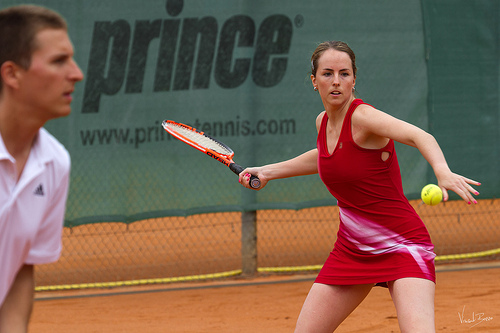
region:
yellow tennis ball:
[420, 180, 445, 206]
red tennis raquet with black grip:
[160, 121, 261, 189]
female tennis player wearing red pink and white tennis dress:
[162, 41, 477, 331]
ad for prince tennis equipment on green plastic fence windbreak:
[73, 0, 305, 151]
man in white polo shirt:
[0, 2, 83, 331]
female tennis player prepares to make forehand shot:
[162, 42, 498, 331]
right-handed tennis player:
[155, 43, 477, 331]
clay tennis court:
[0, 1, 498, 331]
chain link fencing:
[35, 198, 499, 300]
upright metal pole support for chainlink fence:
[240, 209, 257, 280]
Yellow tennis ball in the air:
[416, 183, 447, 204]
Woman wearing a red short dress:
[312, 102, 442, 284]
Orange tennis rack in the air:
[157, 110, 268, 190]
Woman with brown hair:
[310, 38, 359, 114]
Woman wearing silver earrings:
[303, 67, 357, 99]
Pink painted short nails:
[438, 176, 494, 207]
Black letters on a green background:
[77, 0, 305, 111]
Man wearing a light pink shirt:
[0, 120, 77, 312]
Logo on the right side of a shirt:
[33, 179, 45, 202]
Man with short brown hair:
[0, 7, 82, 142]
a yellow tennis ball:
[419, 183, 444, 206]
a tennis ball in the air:
[417, 180, 444, 207]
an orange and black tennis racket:
[160, 117, 261, 191]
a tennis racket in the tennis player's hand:
[158, 118, 269, 193]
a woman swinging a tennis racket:
[157, 40, 482, 331]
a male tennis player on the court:
[1, 5, 87, 331]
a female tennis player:
[159, 41, 484, 331]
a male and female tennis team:
[2, 6, 482, 331]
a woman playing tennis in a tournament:
[157, 5, 482, 332]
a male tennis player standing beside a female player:
[1, 5, 85, 332]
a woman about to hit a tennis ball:
[162, 40, 480, 332]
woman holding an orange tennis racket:
[163, 116, 261, 191]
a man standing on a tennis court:
[2, 8, 84, 332]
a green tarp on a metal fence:
[3, 0, 499, 225]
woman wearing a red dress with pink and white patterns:
[312, 95, 437, 283]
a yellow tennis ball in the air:
[421, 184, 443, 206]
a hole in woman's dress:
[381, 150, 391, 164]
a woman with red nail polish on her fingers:
[441, 181, 481, 206]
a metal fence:
[33, 198, 498, 290]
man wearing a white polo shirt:
[0, 129, 70, 308]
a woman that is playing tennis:
[205, 45, 482, 313]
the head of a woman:
[304, 32, 359, 107]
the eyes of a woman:
[321, 66, 350, 79]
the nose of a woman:
[325, 75, 347, 88]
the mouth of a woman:
[325, 83, 345, 102]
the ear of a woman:
[297, 75, 322, 94]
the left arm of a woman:
[365, 105, 451, 186]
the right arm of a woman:
[252, 150, 320, 183]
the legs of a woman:
[303, 253, 432, 328]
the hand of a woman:
[227, 168, 267, 195]